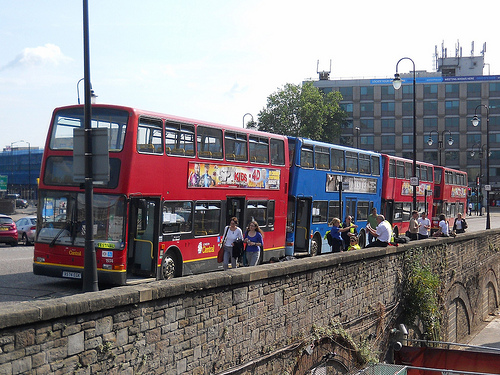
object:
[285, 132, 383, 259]
section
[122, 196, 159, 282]
door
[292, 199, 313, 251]
door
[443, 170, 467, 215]
bus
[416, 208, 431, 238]
man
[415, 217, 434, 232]
shirt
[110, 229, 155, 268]
railing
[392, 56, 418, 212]
streetlight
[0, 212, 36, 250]
cars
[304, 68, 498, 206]
building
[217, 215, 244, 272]
person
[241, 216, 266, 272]
person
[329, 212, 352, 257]
person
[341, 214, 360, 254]
person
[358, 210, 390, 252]
person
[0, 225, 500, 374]
wall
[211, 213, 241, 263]
woman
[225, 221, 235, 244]
sweater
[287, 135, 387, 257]
bus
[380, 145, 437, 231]
bus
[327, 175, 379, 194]
banner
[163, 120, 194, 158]
window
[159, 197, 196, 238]
window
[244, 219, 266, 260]
woman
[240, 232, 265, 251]
shirt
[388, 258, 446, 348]
bush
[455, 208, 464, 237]
people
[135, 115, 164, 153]
window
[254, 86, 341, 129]
tree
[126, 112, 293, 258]
side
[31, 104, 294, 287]
bus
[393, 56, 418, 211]
lamp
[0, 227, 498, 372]
bridge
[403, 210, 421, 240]
people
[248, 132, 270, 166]
window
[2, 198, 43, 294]
lot